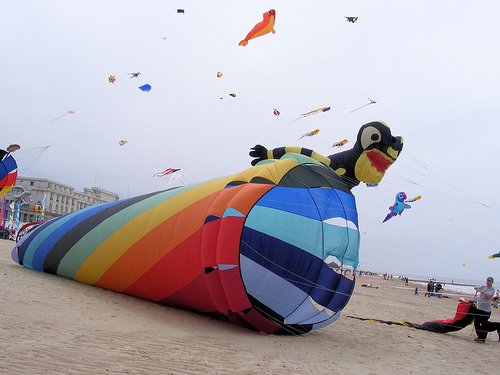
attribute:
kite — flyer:
[221, 11, 285, 56]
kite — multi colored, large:
[24, 149, 389, 356]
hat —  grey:
[484, 273, 497, 283]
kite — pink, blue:
[388, 192, 430, 227]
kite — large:
[6, 118, 407, 338]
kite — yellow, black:
[248, 120, 405, 189]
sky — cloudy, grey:
[410, 29, 476, 127]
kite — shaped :
[383, 189, 414, 221]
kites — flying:
[296, 103, 333, 118]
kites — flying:
[351, 97, 378, 111]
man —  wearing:
[465, 268, 499, 341]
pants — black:
[463, 303, 493, 338]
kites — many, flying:
[53, 3, 386, 118]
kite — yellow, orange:
[237, 8, 276, 45]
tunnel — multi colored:
[9, 102, 410, 340]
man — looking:
[459, 267, 499, 357]